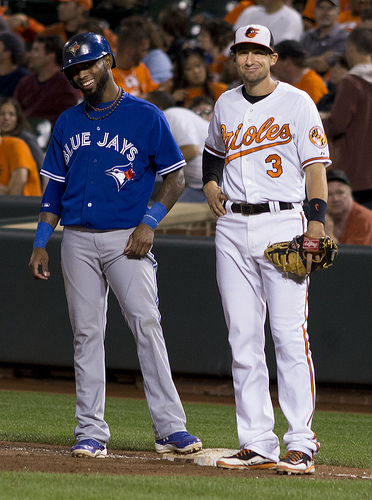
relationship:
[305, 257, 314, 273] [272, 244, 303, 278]
finger out of mitt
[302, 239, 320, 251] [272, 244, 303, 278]
red logo on mitt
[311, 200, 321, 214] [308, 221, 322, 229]
nike logo on wrist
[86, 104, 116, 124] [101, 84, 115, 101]
necklace around neck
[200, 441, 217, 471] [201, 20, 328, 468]
base between player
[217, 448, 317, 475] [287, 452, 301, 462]
shoes with orange laces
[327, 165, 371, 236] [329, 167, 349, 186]
fan wearing black hat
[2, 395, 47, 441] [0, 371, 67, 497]
grass on field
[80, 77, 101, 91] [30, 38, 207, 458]
smiling face of ballplayer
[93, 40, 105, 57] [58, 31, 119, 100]
blue helmet on head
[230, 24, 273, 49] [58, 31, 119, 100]
hat on players head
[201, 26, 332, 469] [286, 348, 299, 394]
player wearing white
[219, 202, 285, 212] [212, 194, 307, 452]
belt on pants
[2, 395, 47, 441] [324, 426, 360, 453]
grass color green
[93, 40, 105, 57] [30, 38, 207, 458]
blue helmet on player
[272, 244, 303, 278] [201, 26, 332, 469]
mitt on player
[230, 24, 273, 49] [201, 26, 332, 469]
hat of player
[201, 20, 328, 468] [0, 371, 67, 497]
player on field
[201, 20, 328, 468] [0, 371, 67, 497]
player standing on field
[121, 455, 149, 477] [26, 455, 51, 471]
ground color brown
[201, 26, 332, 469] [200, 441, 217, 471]
player standing near base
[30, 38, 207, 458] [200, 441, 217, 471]
runner standing near base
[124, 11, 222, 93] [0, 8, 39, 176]
spectators in stands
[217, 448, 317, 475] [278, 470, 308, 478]
shoes have spikes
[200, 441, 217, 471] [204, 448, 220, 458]
base has dirt